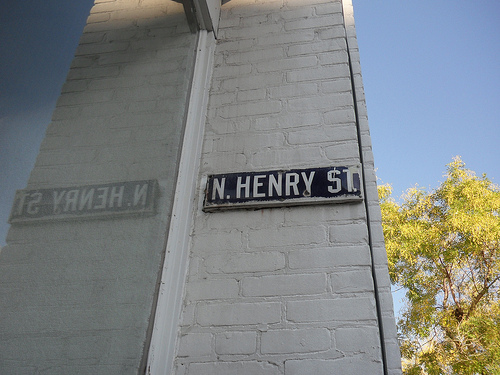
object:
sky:
[354, 1, 499, 216]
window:
[2, 2, 197, 373]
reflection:
[0, 80, 161, 332]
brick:
[245, 224, 331, 249]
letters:
[268, 171, 284, 196]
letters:
[300, 171, 316, 197]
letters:
[211, 177, 226, 200]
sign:
[202, 162, 363, 218]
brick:
[196, 301, 282, 326]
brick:
[285, 90, 353, 112]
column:
[168, 1, 402, 372]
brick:
[288, 244, 370, 270]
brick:
[223, 46, 284, 63]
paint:
[203, 196, 363, 212]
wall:
[152, 0, 406, 374]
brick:
[236, 88, 266, 102]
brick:
[258, 28, 315, 45]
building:
[139, 0, 400, 373]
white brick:
[258, 327, 335, 354]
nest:
[451, 305, 465, 323]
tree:
[372, 154, 500, 374]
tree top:
[376, 155, 500, 244]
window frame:
[138, 0, 225, 375]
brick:
[241, 272, 329, 298]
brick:
[201, 248, 290, 275]